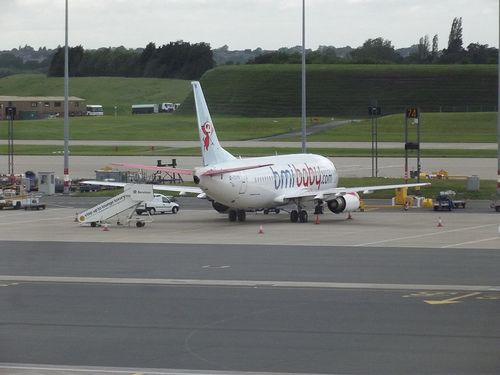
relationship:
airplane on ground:
[78, 80, 432, 222] [0, 72, 499, 373]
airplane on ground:
[78, 80, 432, 222] [2, 186, 499, 374]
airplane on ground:
[104, 74, 441, 234] [2, 186, 499, 374]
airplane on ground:
[78, 80, 432, 222] [2, 149, 499, 374]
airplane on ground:
[78, 80, 432, 222] [7, 186, 485, 356]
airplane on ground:
[122, 80, 436, 250] [4, 107, 496, 370]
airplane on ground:
[104, 74, 441, 234] [53, 197, 252, 359]